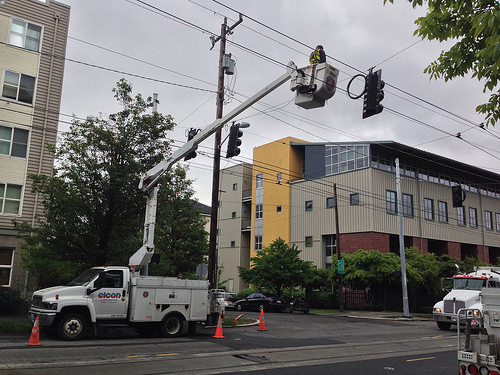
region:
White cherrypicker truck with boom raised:
[26, 60, 341, 342]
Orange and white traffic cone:
[21, 313, 43, 348]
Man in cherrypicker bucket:
[307, 43, 327, 66]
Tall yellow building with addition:
[248, 136, 308, 288]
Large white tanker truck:
[428, 263, 498, 329]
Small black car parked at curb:
[230, 289, 289, 313]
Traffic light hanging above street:
[361, 64, 386, 121]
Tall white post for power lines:
[391, 155, 412, 319]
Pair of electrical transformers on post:
[218, 50, 236, 77]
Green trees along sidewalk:
[237, 235, 495, 307]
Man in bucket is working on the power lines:
[288, 39, 340, 107]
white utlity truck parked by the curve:
[29, 256, 209, 333]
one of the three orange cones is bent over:
[211, 303, 273, 338]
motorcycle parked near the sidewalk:
[284, 289, 315, 313]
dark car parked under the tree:
[235, 278, 285, 313]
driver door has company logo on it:
[95, 271, 130, 317]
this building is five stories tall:
[0, 5, 47, 310]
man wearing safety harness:
[305, 43, 333, 63]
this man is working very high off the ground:
[277, 38, 342, 116]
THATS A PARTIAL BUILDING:
[0, 0, 71, 311]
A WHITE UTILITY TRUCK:
[27, 43, 342, 342]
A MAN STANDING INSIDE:
[307, 44, 329, 62]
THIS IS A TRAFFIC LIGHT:
[360, 68, 385, 120]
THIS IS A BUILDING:
[215, 133, 498, 311]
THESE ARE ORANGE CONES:
[208, 306, 269, 340]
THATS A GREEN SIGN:
[333, 254, 344, 276]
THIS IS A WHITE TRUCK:
[430, 262, 497, 329]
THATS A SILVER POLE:
[392, 150, 413, 320]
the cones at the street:
[14, 306, 294, 355]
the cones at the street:
[15, 302, 279, 349]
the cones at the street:
[10, 298, 275, 343]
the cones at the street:
[12, 300, 274, 353]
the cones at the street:
[10, 303, 275, 347]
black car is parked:
[202, 275, 330, 352]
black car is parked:
[213, 272, 298, 317]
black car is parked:
[217, 285, 294, 317]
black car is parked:
[215, 270, 302, 323]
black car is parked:
[217, 271, 309, 333]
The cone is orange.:
[211, 308, 227, 340]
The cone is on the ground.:
[211, 311, 224, 341]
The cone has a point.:
[211, 312, 227, 339]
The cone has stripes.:
[212, 313, 226, 338]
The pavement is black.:
[288, 317, 348, 342]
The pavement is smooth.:
[281, 324, 346, 341]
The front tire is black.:
[56, 310, 91, 340]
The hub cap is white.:
[64, 317, 81, 337]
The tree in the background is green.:
[233, 235, 327, 294]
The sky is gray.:
[333, 9, 386, 40]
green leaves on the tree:
[112, 203, 125, 222]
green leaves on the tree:
[299, 264, 315, 293]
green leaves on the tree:
[270, 288, 285, 309]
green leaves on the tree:
[289, 263, 311, 290]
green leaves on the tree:
[363, 257, 377, 277]